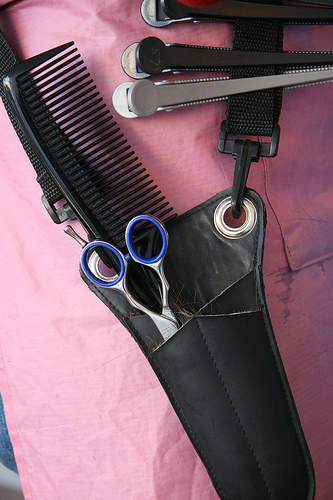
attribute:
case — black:
[1, 1, 331, 496]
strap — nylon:
[213, 36, 297, 143]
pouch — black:
[72, 191, 323, 409]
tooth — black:
[21, 57, 84, 97]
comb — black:
[0, 38, 183, 322]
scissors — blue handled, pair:
[62, 214, 183, 343]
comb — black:
[1, 41, 169, 251]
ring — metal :
[209, 195, 260, 243]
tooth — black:
[28, 39, 76, 57]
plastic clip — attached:
[217, 121, 279, 217]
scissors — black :
[78, 212, 177, 340]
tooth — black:
[15, 47, 81, 86]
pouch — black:
[93, 183, 318, 494]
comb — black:
[40, 55, 103, 213]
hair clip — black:
[138, 0, 331, 30]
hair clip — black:
[118, 34, 332, 80]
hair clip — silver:
[109, 63, 330, 120]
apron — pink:
[145, 114, 330, 277]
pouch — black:
[72, 211, 330, 498]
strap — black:
[209, 1, 294, 213]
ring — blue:
[127, 216, 166, 263]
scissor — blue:
[63, 213, 179, 343]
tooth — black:
[24, 39, 108, 74]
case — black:
[78, 185, 320, 498]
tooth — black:
[43, 84, 108, 116]